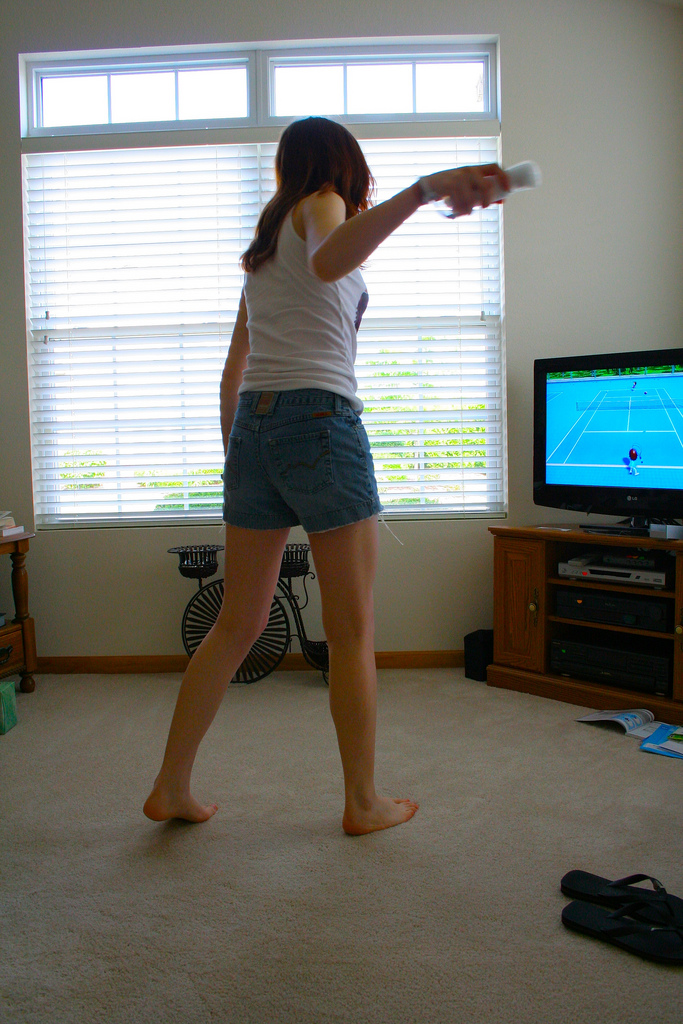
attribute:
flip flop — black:
[559, 859, 679, 923]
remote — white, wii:
[416, 153, 548, 223]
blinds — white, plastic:
[22, 137, 506, 531]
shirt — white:
[233, 207, 372, 405]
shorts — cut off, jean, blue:
[213, 380, 384, 538]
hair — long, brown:
[237, 114, 381, 271]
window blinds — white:
[13, 133, 504, 520]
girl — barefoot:
[118, 108, 555, 855]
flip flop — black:
[547, 895, 681, 984]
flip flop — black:
[560, 848, 681, 934]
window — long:
[26, 46, 495, 130]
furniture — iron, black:
[165, 525, 343, 676]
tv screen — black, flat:
[518, 332, 676, 515]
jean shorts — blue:
[217, 381, 390, 537]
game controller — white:
[438, 168, 544, 215]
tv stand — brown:
[470, 518, 681, 714]